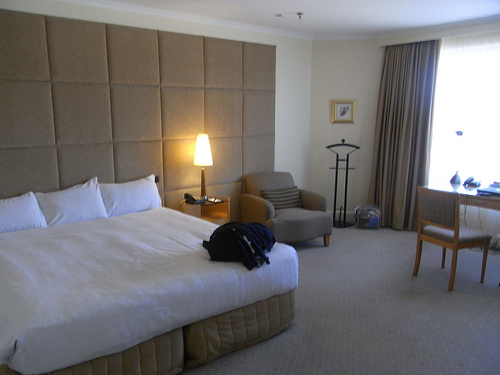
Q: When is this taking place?
A: Daytime.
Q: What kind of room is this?
A: Bedroom.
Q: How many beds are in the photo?
A: One.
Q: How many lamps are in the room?
A: One.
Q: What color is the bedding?
A: White.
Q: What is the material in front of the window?
A: Curtains.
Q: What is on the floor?
A: Carpet.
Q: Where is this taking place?
A: In a bedroom.